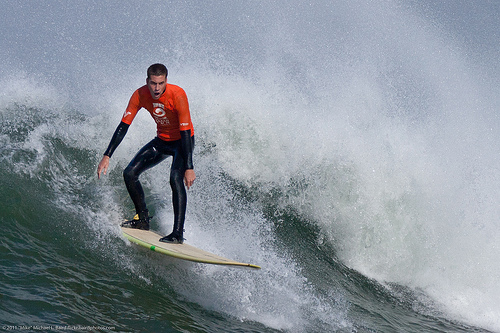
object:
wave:
[25, 94, 484, 297]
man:
[89, 59, 200, 245]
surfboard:
[108, 217, 265, 271]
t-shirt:
[120, 83, 198, 144]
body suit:
[97, 61, 212, 235]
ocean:
[4, 94, 499, 333]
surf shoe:
[156, 230, 186, 246]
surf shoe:
[117, 212, 153, 229]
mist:
[233, 38, 495, 78]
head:
[144, 64, 171, 98]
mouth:
[153, 91, 161, 96]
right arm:
[93, 90, 140, 173]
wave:
[9, 92, 337, 263]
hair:
[144, 62, 171, 79]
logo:
[153, 108, 166, 119]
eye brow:
[157, 79, 165, 83]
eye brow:
[148, 78, 155, 84]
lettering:
[3, 324, 121, 331]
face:
[147, 74, 166, 99]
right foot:
[119, 215, 152, 229]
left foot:
[159, 232, 186, 243]